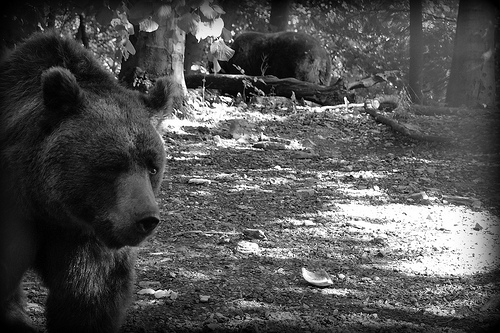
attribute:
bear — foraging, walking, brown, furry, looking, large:
[12, 22, 187, 291]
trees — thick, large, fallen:
[143, 11, 195, 81]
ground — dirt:
[240, 113, 347, 210]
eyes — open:
[108, 153, 165, 180]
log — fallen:
[218, 71, 343, 112]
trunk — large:
[397, 36, 433, 74]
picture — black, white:
[5, 11, 499, 300]